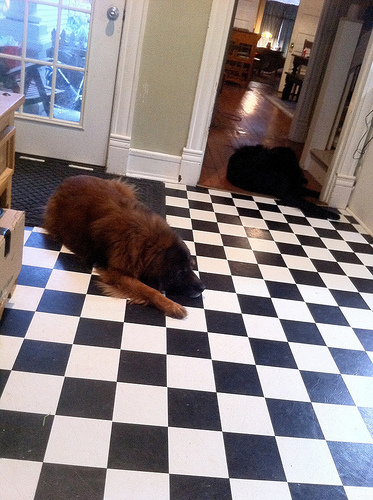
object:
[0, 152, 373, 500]
floor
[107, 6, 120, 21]
knob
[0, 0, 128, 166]
door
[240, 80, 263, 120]
reflection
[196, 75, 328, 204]
floor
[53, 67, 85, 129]
panes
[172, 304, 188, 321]
paw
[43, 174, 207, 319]
dog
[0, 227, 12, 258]
tape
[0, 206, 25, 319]
box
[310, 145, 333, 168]
step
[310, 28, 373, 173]
stairwell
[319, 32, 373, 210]
trim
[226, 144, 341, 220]
dog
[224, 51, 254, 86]
chair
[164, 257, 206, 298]
face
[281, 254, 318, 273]
tiles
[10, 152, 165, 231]
mat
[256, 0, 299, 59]
curtains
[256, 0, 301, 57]
window